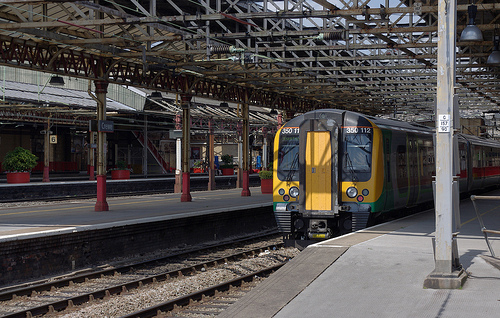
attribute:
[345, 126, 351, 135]
number — 3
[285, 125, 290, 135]
number — 5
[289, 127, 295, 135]
number — 0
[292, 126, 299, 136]
number — 1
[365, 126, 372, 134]
number — 2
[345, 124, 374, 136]
number — 350 112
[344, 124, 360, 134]
number — 350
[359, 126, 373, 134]
number — 112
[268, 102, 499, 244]
train — yellow, inside station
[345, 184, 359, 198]
headlight — silver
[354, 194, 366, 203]
light — red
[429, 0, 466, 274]
pole — metal, steel, grey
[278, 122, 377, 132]
stripe — red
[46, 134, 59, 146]
sign — white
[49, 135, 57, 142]
number — 6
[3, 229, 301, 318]
train tracks — metal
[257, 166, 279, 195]
plant — large, green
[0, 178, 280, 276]
platform — gray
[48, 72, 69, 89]
light — overhead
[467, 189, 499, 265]
railing — metal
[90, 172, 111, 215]
base — red